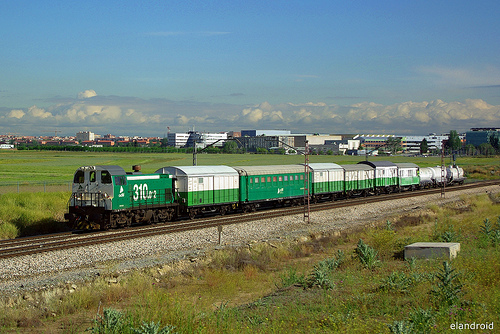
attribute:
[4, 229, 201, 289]
gravel — white, grey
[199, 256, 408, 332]
grass — green 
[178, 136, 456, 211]
train — green, white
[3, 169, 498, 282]
tracks — train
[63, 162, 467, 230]
train — green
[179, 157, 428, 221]
cars — green, white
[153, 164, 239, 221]
train car — green , white 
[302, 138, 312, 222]
poles — electrical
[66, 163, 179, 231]
engine — green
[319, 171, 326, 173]
paint — white 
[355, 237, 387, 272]
bush — small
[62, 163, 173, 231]
car — green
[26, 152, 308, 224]
train — white, green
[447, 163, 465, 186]
tanker car — silver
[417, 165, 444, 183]
tanker car — silver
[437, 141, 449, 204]
poles — electrical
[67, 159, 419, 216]
train — green, white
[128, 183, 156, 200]
numbers — large, white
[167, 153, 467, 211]
cars — green, white